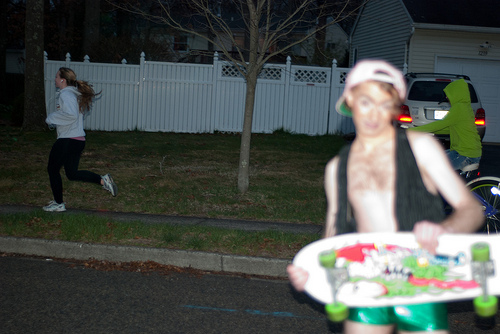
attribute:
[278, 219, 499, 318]
skateboard — white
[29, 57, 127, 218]
woman — jogging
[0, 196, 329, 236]
sidewalk — concrete, gray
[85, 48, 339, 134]
fence — plastic, white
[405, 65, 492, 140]
car — green, white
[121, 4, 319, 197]
tree — small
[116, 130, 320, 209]
grass — green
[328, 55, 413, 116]
hat — backwards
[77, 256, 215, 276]
leaves — brown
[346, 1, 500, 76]
house — yellow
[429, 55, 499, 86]
garage — white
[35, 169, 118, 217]
shoes — white